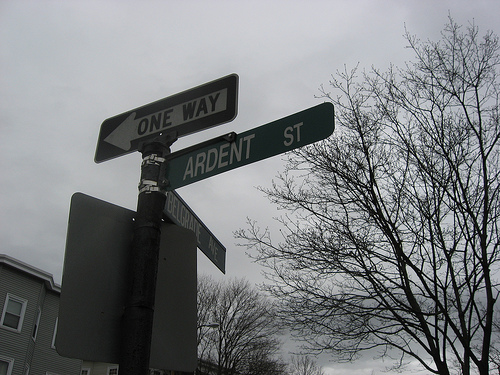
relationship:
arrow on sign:
[105, 87, 229, 152] [74, 59, 372, 208]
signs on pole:
[53, 71, 335, 370] [133, 151, 170, 362]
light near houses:
[199, 311, 223, 338] [0, 249, 282, 373]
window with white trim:
[3, 295, 22, 329] [28, 302, 43, 342]